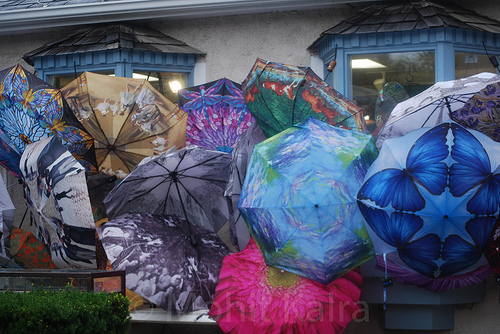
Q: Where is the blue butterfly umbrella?
A: On right.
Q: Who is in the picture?
A: No one.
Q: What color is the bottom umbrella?
A: Pink.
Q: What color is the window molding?
A: Blue.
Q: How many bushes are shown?
A: One.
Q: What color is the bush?
A: Green.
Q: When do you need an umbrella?
A: Rain.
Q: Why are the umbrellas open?
A: Show design.